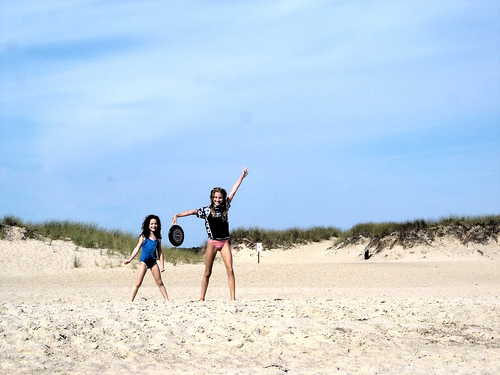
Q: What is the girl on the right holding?
A: A frisbee.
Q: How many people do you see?
A: 2.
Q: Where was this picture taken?
A: The beach.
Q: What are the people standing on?
A: Sand.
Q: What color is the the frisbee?
A: Black.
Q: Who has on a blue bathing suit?
A: The girl to the left.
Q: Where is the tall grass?
A: Behind the people.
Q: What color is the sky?
A: Blue.